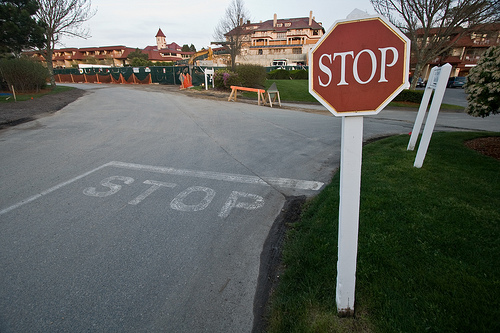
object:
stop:
[316, 44, 400, 88]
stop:
[85, 166, 267, 223]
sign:
[303, 13, 418, 115]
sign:
[409, 10, 468, 170]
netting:
[55, 71, 155, 84]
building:
[141, 27, 188, 61]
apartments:
[51, 46, 191, 81]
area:
[0, 94, 73, 125]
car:
[450, 73, 466, 90]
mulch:
[466, 136, 500, 153]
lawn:
[398, 191, 496, 294]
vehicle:
[186, 46, 217, 66]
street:
[152, 113, 316, 163]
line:
[0, 155, 86, 224]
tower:
[154, 28, 167, 39]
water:
[256, 255, 269, 273]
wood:
[330, 119, 368, 303]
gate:
[154, 67, 178, 85]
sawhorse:
[228, 82, 265, 104]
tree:
[467, 49, 500, 113]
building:
[224, 19, 318, 47]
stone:
[247, 55, 270, 68]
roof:
[81, 45, 121, 50]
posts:
[409, 95, 445, 170]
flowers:
[469, 67, 482, 78]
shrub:
[211, 66, 245, 92]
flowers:
[223, 71, 231, 87]